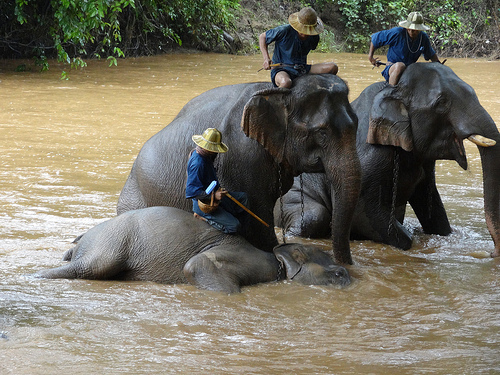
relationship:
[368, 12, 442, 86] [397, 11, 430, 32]
person wearing hat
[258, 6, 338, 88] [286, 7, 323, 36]
person wearing hat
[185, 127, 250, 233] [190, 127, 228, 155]
person wearing hat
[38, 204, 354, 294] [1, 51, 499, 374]
elephant laying in water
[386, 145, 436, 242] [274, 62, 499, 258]
chains draping elephant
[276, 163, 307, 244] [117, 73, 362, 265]
chains draping elephant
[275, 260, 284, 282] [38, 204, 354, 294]
chains draping elephant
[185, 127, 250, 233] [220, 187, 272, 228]
person holding stick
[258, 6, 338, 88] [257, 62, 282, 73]
person holding stick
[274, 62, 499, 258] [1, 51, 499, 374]
elephant walking through water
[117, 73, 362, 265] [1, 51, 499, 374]
elephant walking through water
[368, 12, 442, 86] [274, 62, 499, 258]
person riding elephant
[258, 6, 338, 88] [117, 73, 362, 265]
person riding elephant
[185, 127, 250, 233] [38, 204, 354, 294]
person riding elephant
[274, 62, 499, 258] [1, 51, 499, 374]
elephant sitting in water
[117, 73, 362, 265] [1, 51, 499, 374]
elephant sitting in water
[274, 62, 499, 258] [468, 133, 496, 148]
elephant has tusk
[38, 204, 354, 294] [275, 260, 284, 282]
elephant has chains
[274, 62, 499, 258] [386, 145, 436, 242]
elephant has chains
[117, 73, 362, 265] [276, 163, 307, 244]
elephant has chains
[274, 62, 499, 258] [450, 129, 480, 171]
elephant has mouth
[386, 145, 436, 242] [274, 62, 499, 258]
chains binding elephant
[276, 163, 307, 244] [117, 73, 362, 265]
chains binding elephant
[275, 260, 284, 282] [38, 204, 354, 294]
chains binding elephant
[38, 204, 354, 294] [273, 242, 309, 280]
elephant has ear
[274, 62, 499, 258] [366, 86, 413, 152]
elephant has ear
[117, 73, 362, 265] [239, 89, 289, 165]
elephant has ear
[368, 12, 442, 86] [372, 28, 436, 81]
person wearing outfit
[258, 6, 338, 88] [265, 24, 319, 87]
person wearing outfit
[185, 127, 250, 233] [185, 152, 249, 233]
person wearing outfit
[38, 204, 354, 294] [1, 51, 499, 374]
elephant fell in water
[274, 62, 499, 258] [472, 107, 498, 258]
elephant has trunk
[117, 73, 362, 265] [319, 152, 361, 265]
elephant has trunk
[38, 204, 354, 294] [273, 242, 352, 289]
elephant has head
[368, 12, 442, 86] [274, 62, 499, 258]
person sitting on elephant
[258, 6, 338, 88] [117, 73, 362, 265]
person sitting on elephant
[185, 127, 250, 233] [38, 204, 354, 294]
person sitting on elephant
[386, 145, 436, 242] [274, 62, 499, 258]
chains are around elephant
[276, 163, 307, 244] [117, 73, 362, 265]
chains are around elephant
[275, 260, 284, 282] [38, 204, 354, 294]
chains are around elephant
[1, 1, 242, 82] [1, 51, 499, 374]
tree branches hanging in water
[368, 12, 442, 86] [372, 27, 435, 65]
person wearing shirt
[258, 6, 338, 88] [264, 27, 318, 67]
person wearing shirt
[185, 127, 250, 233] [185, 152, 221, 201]
person wearing shirt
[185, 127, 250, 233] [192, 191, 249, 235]
person wearing jeans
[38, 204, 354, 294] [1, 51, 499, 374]
elephant lying down in water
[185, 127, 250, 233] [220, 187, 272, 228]
person has stick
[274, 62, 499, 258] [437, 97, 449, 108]
elephant has eye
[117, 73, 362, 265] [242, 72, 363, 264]
elephant has head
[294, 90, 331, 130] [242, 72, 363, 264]
dent in head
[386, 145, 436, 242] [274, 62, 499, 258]
chains are on elephant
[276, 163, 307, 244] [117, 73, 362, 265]
chains are on elephant